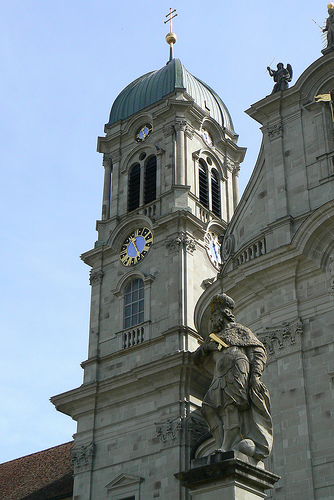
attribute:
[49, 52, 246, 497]
building — old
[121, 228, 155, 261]
clock — gold, time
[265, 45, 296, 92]
statue — gray, angel, high, cement, saint, metal, granite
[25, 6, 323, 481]
building — stone, tall, old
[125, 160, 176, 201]
window — arched, black, divided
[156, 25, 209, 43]
shingles — brown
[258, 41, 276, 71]
sword — golden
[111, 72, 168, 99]
roof — blue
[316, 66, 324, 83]
tower — gray, gothic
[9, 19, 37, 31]
sky — blue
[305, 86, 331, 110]
flag — gold, statue